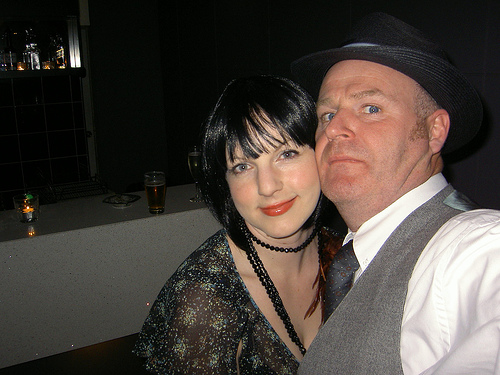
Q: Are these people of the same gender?
A: No, they are both male and female.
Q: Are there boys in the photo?
A: No, there are no boys.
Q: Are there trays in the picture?
A: No, there are no trays.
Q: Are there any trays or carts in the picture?
A: No, there are no trays or carts.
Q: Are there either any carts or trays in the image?
A: No, there are no trays or carts.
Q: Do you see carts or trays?
A: No, there are no trays or carts.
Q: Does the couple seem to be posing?
A: Yes, the couple is posing.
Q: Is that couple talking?
A: No, the couple is posing.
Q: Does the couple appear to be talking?
A: No, the couple is posing.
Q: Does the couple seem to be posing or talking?
A: The couple is posing.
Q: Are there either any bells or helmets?
A: No, there are no helmets or bells.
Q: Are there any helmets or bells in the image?
A: No, there are no helmets or bells.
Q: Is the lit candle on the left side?
A: Yes, the candle is on the left of the image.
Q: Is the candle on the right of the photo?
A: No, the candle is on the left of the image.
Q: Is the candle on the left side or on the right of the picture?
A: The candle is on the left of the image.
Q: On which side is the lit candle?
A: The candle is on the left of the image.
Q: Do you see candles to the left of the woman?
A: Yes, there is a candle to the left of the woman.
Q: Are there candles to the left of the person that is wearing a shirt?
A: Yes, there is a candle to the left of the woman.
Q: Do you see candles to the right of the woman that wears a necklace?
A: No, the candle is to the left of the woman.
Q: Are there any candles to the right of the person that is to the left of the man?
A: No, the candle is to the left of the woman.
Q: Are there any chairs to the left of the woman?
A: No, there is a candle to the left of the woman.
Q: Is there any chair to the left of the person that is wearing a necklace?
A: No, there is a candle to the left of the woman.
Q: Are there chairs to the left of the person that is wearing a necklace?
A: No, there is a candle to the left of the woman.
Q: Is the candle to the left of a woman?
A: Yes, the candle is to the left of a woman.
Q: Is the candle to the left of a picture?
A: No, the candle is to the left of a woman.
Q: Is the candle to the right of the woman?
A: No, the candle is to the left of the woman.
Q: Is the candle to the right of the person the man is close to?
A: No, the candle is to the left of the woman.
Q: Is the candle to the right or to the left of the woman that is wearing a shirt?
A: The candle is to the left of the woman.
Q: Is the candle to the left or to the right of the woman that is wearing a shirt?
A: The candle is to the left of the woman.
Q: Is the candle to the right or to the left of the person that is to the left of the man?
A: The candle is to the left of the woman.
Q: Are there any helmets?
A: No, there are no helmets.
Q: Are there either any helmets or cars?
A: No, there are no helmets or cars.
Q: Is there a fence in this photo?
A: No, there are no fences.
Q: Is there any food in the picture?
A: No, there is no food.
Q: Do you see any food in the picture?
A: No, there is no food.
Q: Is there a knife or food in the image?
A: No, there are no food or knives.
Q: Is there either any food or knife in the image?
A: No, there are no food or knives.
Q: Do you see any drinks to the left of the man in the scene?
A: Yes, there is a drink to the left of the man.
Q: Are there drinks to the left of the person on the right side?
A: Yes, there is a drink to the left of the man.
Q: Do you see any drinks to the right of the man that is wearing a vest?
A: No, the drink is to the left of the man.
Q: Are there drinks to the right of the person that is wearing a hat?
A: No, the drink is to the left of the man.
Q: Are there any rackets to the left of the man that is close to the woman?
A: No, there is a drink to the left of the man.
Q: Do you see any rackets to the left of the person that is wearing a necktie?
A: No, there is a drink to the left of the man.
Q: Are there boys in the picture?
A: No, there are no boys.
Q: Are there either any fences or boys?
A: No, there are no boys or fences.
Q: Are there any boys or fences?
A: No, there are no boys or fences.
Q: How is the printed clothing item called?
A: The clothing item is a shirt.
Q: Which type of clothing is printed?
A: The clothing is a shirt.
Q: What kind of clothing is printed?
A: The clothing is a shirt.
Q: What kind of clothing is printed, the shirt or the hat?
A: The shirt is printed.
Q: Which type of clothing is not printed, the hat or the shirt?
A: The hat is not printed.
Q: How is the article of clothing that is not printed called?
A: The clothing item is a hat.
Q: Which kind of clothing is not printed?
A: The clothing is a hat.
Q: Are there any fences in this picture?
A: No, there are no fences.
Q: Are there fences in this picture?
A: No, there are no fences.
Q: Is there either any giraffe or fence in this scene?
A: No, there are no fences or giraffes.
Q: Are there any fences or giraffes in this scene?
A: No, there are no fences or giraffes.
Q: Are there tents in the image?
A: No, there are no tents.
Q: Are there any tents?
A: No, there are no tents.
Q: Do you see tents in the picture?
A: No, there are no tents.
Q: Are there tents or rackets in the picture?
A: No, there are no tents or rackets.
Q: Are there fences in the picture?
A: No, there are no fences.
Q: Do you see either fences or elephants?
A: No, there are no fences or elephants.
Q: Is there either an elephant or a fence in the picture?
A: No, there are no fences or elephants.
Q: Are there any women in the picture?
A: Yes, there is a woman.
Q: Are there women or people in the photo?
A: Yes, there is a woman.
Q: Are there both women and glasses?
A: Yes, there are both a woman and glasses.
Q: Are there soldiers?
A: No, there are no soldiers.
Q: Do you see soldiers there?
A: No, there are no soldiers.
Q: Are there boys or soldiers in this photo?
A: No, there are no soldiers or boys.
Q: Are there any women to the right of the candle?
A: Yes, there is a woman to the right of the candle.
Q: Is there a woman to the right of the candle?
A: Yes, there is a woman to the right of the candle.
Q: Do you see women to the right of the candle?
A: Yes, there is a woman to the right of the candle.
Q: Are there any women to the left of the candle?
A: No, the woman is to the right of the candle.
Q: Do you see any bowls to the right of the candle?
A: No, there is a woman to the right of the candle.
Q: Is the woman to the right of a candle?
A: Yes, the woman is to the right of a candle.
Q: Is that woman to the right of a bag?
A: No, the woman is to the right of a candle.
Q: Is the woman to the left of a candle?
A: No, the woman is to the right of a candle.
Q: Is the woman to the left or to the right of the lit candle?
A: The woman is to the right of the candle.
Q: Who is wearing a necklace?
A: The woman is wearing a necklace.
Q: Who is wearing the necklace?
A: The woman is wearing a necklace.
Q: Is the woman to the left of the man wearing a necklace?
A: Yes, the woman is wearing a necklace.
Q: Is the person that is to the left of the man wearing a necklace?
A: Yes, the woman is wearing a necklace.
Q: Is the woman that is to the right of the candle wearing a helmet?
A: No, the woman is wearing a necklace.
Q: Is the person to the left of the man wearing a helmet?
A: No, the woman is wearing a necklace.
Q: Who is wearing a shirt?
A: The woman is wearing a shirt.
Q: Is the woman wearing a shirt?
A: Yes, the woman is wearing a shirt.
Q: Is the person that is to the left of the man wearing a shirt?
A: Yes, the woman is wearing a shirt.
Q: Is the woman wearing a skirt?
A: No, the woman is wearing a shirt.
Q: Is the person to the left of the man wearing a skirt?
A: No, the woman is wearing a shirt.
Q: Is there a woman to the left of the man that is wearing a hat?
A: Yes, there is a woman to the left of the man.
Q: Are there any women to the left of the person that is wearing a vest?
A: Yes, there is a woman to the left of the man.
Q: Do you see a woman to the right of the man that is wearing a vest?
A: No, the woman is to the left of the man.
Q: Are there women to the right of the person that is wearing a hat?
A: No, the woman is to the left of the man.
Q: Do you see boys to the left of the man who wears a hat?
A: No, there is a woman to the left of the man.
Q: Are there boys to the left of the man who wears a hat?
A: No, there is a woman to the left of the man.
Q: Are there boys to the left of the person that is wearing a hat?
A: No, there is a woman to the left of the man.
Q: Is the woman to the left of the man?
A: Yes, the woman is to the left of the man.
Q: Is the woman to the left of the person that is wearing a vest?
A: Yes, the woman is to the left of the man.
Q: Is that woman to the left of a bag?
A: No, the woman is to the left of the man.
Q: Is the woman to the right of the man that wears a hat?
A: No, the woman is to the left of the man.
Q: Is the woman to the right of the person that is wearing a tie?
A: No, the woman is to the left of the man.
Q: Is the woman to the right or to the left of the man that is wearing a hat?
A: The woman is to the left of the man.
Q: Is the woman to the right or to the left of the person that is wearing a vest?
A: The woman is to the left of the man.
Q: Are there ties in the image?
A: Yes, there is a tie.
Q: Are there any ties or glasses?
A: Yes, there is a tie.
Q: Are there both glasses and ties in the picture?
A: Yes, there are both a tie and glasses.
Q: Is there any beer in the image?
A: Yes, there is beer.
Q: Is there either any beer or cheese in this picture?
A: Yes, there is beer.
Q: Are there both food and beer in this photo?
A: No, there is beer but no food.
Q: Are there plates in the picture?
A: No, there are no plates.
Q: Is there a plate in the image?
A: No, there are no plates.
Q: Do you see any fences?
A: No, there are no fences.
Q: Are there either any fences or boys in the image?
A: No, there are no fences or boys.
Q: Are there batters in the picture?
A: No, there are no batters.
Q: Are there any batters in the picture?
A: No, there are no batters.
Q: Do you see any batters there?
A: No, there are no batters.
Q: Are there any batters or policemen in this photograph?
A: No, there are no batters or policemen.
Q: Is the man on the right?
A: Yes, the man is on the right of the image.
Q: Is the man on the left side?
A: No, the man is on the right of the image.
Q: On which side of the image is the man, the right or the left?
A: The man is on the right of the image.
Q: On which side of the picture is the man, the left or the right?
A: The man is on the right of the image.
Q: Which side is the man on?
A: The man is on the right of the image.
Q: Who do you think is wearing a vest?
A: The man is wearing a vest.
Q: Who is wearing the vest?
A: The man is wearing a vest.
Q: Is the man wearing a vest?
A: Yes, the man is wearing a vest.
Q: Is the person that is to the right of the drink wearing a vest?
A: Yes, the man is wearing a vest.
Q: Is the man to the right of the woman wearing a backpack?
A: No, the man is wearing a vest.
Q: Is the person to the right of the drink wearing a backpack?
A: No, the man is wearing a vest.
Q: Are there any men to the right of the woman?
A: Yes, there is a man to the right of the woman.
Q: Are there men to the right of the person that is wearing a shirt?
A: Yes, there is a man to the right of the woman.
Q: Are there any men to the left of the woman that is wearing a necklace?
A: No, the man is to the right of the woman.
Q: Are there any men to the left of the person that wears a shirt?
A: No, the man is to the right of the woman.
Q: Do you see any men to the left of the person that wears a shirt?
A: No, the man is to the right of the woman.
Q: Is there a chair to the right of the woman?
A: No, there is a man to the right of the woman.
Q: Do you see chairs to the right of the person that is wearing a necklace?
A: No, there is a man to the right of the woman.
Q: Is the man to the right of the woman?
A: Yes, the man is to the right of the woman.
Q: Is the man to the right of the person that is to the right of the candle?
A: Yes, the man is to the right of the woman.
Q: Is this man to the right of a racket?
A: No, the man is to the right of the woman.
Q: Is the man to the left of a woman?
A: No, the man is to the right of a woman.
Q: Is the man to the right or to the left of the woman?
A: The man is to the right of the woman.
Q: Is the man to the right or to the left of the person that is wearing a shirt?
A: The man is to the right of the woman.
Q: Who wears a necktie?
A: The man wears a necktie.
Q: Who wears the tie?
A: The man wears a necktie.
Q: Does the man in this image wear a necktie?
A: Yes, the man wears a necktie.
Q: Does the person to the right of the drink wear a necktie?
A: Yes, the man wears a necktie.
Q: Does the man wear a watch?
A: No, the man wears a necktie.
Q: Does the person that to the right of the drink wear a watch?
A: No, the man wears a necktie.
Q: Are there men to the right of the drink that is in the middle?
A: Yes, there is a man to the right of the drink.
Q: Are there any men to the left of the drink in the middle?
A: No, the man is to the right of the drink.